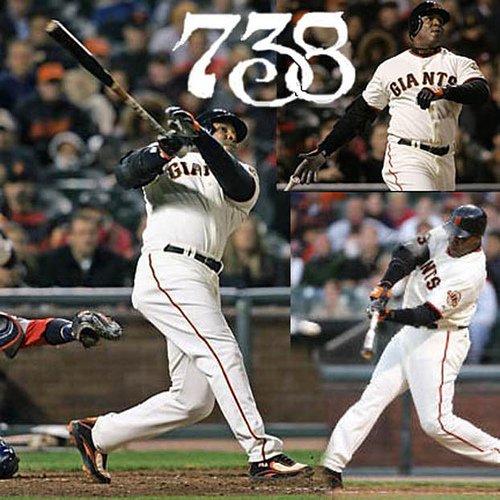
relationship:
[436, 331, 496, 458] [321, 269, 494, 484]
stripe stitched on pants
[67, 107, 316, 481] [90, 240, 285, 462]
batter wearing long pants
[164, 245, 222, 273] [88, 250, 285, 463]
belt sewn on pants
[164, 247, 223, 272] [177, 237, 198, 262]
belt underneath loop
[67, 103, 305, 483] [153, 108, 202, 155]
batter wearing gloves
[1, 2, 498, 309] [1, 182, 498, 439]
crowd sitting in stands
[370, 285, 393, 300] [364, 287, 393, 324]
panel on top gloves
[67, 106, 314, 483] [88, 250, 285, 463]
man wearing pants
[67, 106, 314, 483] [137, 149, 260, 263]
man wearing shirt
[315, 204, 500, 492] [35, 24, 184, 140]
person swinging bat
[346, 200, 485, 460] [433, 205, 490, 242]
person wearing helmet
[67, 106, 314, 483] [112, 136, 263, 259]
man wearing shirt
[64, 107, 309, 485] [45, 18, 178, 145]
man swinging bat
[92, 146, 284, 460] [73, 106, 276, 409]
uniform on man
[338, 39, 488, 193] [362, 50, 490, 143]
man wearing shirt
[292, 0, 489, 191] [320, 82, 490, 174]
man wearing shirt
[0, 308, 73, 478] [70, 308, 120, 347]
person wearing baseball glove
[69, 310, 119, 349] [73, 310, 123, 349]
hand has a baseball glove